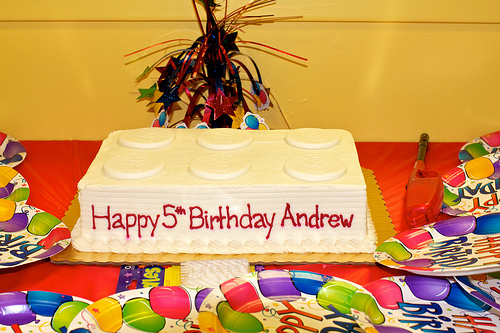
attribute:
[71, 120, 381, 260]
birthday cake — a kid's 5th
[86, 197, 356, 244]
text — made of frosting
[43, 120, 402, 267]
cake — on a piece of cardboard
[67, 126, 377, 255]
white frosting — covers the cake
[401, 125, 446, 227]
lighter — red and black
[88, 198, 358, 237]
frosting — red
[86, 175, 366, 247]
frosting — red, white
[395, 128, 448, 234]
lighter — red, candle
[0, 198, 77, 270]
plate — colorful, paper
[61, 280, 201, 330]
plate — colorful, paper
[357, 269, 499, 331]
plate — colorful, paper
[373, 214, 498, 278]
plate — colorful, paper, party, dining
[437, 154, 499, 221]
plate — colorful, paper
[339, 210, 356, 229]
letter — red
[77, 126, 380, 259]
cake — white, shaped like a lego-block, birthday, designed, lego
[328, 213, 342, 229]
letter — red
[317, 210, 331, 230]
letter — red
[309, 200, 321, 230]
letter — red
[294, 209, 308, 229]
letter — red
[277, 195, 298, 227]
letter — red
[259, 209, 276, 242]
letter — red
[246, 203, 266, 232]
letter — red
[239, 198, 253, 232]
letter — red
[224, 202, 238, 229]
letter — red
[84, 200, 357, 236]
icing — red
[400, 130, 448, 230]
lighter — red, black, bbq, extended, electronic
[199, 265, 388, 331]
plate — colorful, paper, happy, birthday, disposable, party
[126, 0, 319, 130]
streamers — colored, birthday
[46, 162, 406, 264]
tray — silver, cake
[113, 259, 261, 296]
candles — white, birthday, pack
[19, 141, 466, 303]
cloth — red, table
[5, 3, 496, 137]
wall — white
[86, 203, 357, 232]
writing — red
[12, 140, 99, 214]
tablecloth — orange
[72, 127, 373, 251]
frosting — white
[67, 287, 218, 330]
plate — party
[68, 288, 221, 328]
design — balloon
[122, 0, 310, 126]
fountain — foil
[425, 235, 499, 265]
words — happy birthday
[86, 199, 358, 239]
writing — happy 5th birthday Andrew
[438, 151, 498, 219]
plate — dining